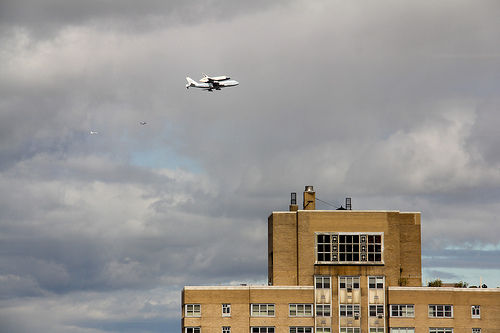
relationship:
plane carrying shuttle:
[185, 76, 238, 93] [199, 74, 230, 83]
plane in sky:
[185, 76, 238, 93] [1, 0, 498, 332]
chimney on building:
[304, 185, 315, 209] [181, 185, 500, 332]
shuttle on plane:
[199, 74, 230, 83] [185, 76, 238, 93]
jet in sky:
[139, 120, 148, 126] [1, 0, 498, 332]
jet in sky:
[90, 130, 99, 136] [1, 0, 498, 332]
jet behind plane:
[139, 120, 148, 126] [185, 76, 238, 93]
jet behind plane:
[90, 130, 99, 136] [185, 76, 238, 93]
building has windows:
[181, 185, 500, 332] [185, 232, 481, 333]